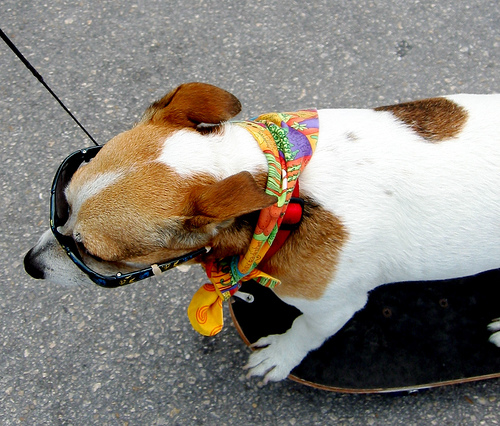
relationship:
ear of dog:
[200, 172, 276, 211] [25, 86, 499, 328]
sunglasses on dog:
[44, 147, 147, 283] [25, 86, 499, 328]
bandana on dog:
[239, 106, 313, 268] [25, 86, 499, 328]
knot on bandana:
[206, 258, 272, 299] [239, 106, 313, 268]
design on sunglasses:
[123, 264, 171, 284] [44, 147, 147, 283]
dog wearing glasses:
[25, 86, 499, 328] [44, 147, 147, 283]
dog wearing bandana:
[25, 86, 499, 328] [239, 106, 313, 268]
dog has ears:
[25, 86, 499, 328] [149, 82, 262, 217]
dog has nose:
[25, 86, 499, 328] [19, 241, 44, 282]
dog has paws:
[25, 86, 499, 328] [249, 333, 297, 388]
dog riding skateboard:
[25, 86, 499, 328] [218, 286, 498, 398]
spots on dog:
[380, 90, 468, 143] [25, 86, 499, 328]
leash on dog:
[256, 190, 310, 256] [25, 86, 499, 328]